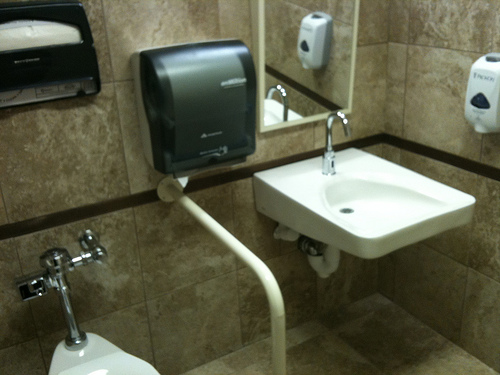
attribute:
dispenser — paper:
[126, 38, 259, 172]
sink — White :
[262, 126, 473, 271]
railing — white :
[153, 168, 293, 372]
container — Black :
[3, 6, 91, 105]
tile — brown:
[140, 300, 254, 355]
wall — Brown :
[2, 2, 378, 365]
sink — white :
[252, 147, 479, 279]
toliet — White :
[32, 328, 129, 374]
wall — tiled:
[387, 4, 497, 319]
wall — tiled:
[20, 9, 366, 340]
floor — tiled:
[212, 322, 441, 372]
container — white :
[458, 49, 499, 139]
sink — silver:
[253, 139, 427, 232]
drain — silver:
[341, 207, 353, 213]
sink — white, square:
[252, 147, 475, 258]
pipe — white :
[308, 244, 340, 276]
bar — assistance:
[167, 182, 299, 372]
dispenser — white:
[459, 44, 499, 141]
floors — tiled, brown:
[353, 320, 425, 360]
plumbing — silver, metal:
[10, 225, 111, 352]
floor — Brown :
[330, 309, 445, 373]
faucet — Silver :
[321, 110, 351, 182]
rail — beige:
[154, 173, 287, 370]